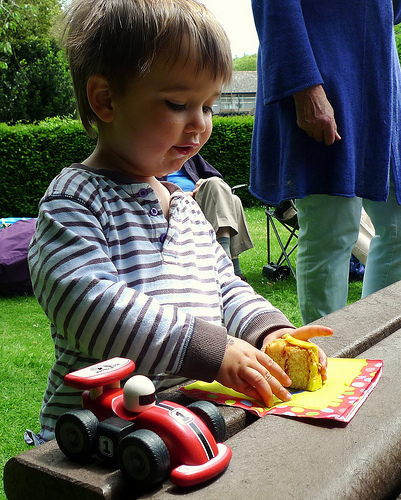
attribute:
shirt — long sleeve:
[28, 160, 300, 376]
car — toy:
[59, 360, 238, 487]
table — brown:
[6, 280, 396, 494]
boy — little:
[37, 34, 237, 378]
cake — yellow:
[253, 319, 340, 390]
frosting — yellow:
[277, 324, 318, 350]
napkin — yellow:
[173, 356, 382, 423]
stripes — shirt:
[37, 169, 215, 366]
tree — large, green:
[7, 37, 42, 98]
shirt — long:
[57, 166, 296, 350]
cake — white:
[263, 333, 323, 391]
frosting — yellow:
[282, 332, 323, 388]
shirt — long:
[250, 1, 400, 205]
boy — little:
[19, 2, 334, 437]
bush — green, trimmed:
[1, 113, 257, 216]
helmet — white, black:
[116, 373, 158, 409]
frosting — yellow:
[308, 342, 322, 386]